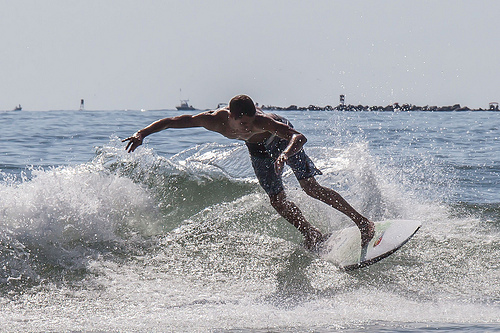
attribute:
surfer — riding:
[178, 24, 362, 229]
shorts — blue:
[235, 146, 310, 185]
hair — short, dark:
[222, 92, 259, 121]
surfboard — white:
[289, 214, 425, 272]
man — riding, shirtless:
[155, 91, 391, 232]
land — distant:
[298, 88, 465, 128]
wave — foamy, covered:
[27, 176, 171, 269]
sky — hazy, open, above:
[64, 9, 343, 91]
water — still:
[290, 63, 500, 175]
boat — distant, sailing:
[10, 98, 48, 126]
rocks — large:
[393, 102, 469, 121]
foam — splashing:
[323, 135, 406, 190]